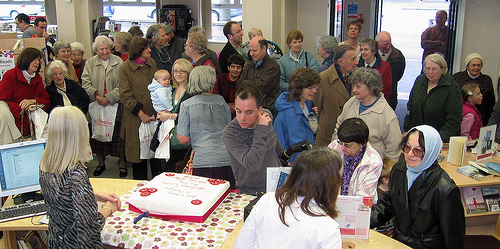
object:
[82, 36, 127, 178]
person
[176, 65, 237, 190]
person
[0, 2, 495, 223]
people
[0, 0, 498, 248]
store